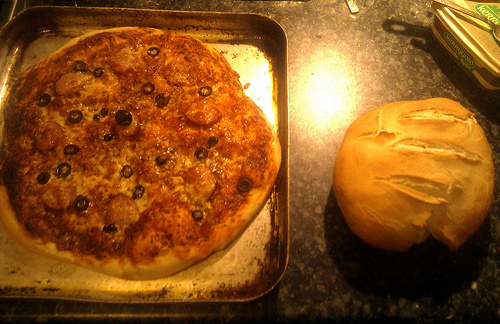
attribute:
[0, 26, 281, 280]
pizza — nice, delicious, tasty, good, flavorful, round, cooked, hot, brown, fresh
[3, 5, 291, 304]
pan — metal, gray, silver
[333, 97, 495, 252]
bread — nice, brown, fresh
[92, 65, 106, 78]
olive — black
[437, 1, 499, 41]
spoon — metal, gray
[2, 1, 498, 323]
counter top — black